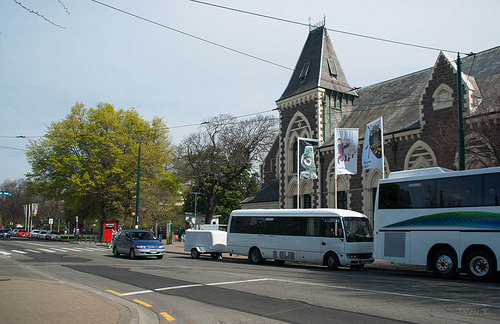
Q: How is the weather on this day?
A: It is clear.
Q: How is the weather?
A: It is clear.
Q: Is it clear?
A: Yes, it is clear.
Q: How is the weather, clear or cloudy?
A: It is clear.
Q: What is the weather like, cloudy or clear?
A: It is clear.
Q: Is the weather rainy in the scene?
A: No, it is clear.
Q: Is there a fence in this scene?
A: No, there are no fences.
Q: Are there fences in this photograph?
A: No, there are no fences.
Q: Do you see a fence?
A: No, there are no fences.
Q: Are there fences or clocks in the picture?
A: No, there are no fences or clocks.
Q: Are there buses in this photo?
A: Yes, there is a bus.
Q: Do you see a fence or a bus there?
A: Yes, there is a bus.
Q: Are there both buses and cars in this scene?
A: Yes, there are both a bus and a car.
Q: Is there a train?
A: No, there are no trains.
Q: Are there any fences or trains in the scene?
A: No, there are no trains or fences.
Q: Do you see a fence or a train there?
A: No, there are no trains or fences.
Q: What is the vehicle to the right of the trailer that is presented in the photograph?
A: The vehicle is a bus.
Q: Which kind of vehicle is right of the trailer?
A: The vehicle is a bus.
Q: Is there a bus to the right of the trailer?
A: Yes, there is a bus to the right of the trailer.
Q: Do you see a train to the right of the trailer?
A: No, there is a bus to the right of the trailer.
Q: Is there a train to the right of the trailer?
A: No, there is a bus to the right of the trailer.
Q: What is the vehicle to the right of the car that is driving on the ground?
A: The vehicle is a bus.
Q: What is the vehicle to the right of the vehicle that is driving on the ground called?
A: The vehicle is a bus.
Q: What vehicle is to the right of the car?
A: The vehicle is a bus.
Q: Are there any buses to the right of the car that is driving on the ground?
A: Yes, there is a bus to the right of the car.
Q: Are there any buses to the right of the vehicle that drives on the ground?
A: Yes, there is a bus to the right of the car.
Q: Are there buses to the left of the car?
A: No, the bus is to the right of the car.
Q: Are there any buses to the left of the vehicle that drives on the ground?
A: No, the bus is to the right of the car.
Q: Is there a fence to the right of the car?
A: No, there is a bus to the right of the car.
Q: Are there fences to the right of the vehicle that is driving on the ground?
A: No, there is a bus to the right of the car.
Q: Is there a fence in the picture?
A: No, there are no fences.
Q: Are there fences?
A: No, there are no fences.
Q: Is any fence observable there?
A: No, there are no fences.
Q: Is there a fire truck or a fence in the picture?
A: No, there are no fences or fire trucks.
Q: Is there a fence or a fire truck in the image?
A: No, there are no fences or fire trucks.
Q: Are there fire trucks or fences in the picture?
A: No, there are no fences or fire trucks.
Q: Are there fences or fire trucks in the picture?
A: No, there are no fences or fire trucks.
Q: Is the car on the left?
A: Yes, the car is on the left of the image.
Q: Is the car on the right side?
A: No, the car is on the left of the image.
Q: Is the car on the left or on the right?
A: The car is on the left of the image.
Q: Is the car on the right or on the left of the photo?
A: The car is on the left of the image.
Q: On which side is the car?
A: The car is on the left of the image.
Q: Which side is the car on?
A: The car is on the left of the image.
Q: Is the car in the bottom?
A: Yes, the car is in the bottom of the image.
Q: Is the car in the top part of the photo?
A: No, the car is in the bottom of the image.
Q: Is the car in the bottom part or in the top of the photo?
A: The car is in the bottom of the image.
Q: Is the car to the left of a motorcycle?
A: No, the car is to the left of the bus.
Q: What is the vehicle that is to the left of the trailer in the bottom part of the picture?
A: The vehicle is a car.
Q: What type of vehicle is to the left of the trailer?
A: The vehicle is a car.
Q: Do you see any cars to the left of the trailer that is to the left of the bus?
A: Yes, there is a car to the left of the trailer.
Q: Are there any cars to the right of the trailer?
A: No, the car is to the left of the trailer.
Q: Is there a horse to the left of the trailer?
A: No, there is a car to the left of the trailer.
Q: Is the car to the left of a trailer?
A: Yes, the car is to the left of a trailer.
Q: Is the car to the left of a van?
A: No, the car is to the left of a trailer.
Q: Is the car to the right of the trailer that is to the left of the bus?
A: No, the car is to the left of the trailer.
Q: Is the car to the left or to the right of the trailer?
A: The car is to the left of the trailer.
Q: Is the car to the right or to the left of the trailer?
A: The car is to the left of the trailer.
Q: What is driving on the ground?
A: The car is driving on the ground.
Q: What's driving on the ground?
A: The car is driving on the ground.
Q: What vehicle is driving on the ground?
A: The vehicle is a car.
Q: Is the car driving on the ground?
A: Yes, the car is driving on the ground.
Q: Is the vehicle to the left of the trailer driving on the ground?
A: Yes, the car is driving on the ground.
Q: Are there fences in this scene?
A: No, there are no fences.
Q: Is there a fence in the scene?
A: No, there are no fences.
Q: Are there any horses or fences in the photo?
A: No, there are no fences or horses.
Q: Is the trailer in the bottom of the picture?
A: Yes, the trailer is in the bottom of the image.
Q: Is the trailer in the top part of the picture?
A: No, the trailer is in the bottom of the image.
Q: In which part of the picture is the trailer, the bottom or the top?
A: The trailer is in the bottom of the image.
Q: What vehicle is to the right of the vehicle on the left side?
A: The vehicle is a trailer.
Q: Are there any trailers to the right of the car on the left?
A: Yes, there is a trailer to the right of the car.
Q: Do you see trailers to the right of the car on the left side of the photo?
A: Yes, there is a trailer to the right of the car.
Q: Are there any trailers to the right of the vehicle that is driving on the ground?
A: Yes, there is a trailer to the right of the car.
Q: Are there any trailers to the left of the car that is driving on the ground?
A: No, the trailer is to the right of the car.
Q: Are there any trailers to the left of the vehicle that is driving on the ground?
A: No, the trailer is to the right of the car.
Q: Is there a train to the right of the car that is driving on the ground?
A: No, there is a trailer to the right of the car.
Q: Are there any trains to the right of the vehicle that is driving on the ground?
A: No, there is a trailer to the right of the car.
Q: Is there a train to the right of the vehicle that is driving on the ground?
A: No, there is a trailer to the right of the car.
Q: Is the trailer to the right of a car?
A: Yes, the trailer is to the right of a car.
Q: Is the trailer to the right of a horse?
A: No, the trailer is to the right of a car.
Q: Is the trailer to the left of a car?
A: No, the trailer is to the right of a car.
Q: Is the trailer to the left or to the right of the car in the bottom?
A: The trailer is to the right of the car.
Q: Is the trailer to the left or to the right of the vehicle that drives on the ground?
A: The trailer is to the right of the car.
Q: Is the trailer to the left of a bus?
A: Yes, the trailer is to the left of a bus.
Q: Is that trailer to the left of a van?
A: No, the trailer is to the left of a bus.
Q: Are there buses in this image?
A: Yes, there is a bus.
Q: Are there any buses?
A: Yes, there is a bus.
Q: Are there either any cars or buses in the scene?
A: Yes, there is a bus.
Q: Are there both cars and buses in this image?
A: Yes, there are both a bus and a car.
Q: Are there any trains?
A: No, there are no trains.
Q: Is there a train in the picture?
A: No, there are no trains.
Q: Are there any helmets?
A: No, there are no helmets.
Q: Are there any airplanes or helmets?
A: No, there are no helmets or airplanes.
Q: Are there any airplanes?
A: No, there are no airplanes.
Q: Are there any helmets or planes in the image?
A: No, there are no planes or helmets.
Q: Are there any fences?
A: No, there are no fences.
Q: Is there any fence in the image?
A: No, there are no fences.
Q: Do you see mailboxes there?
A: No, there are no mailboxes.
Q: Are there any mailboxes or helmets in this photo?
A: No, there are no mailboxes or helmets.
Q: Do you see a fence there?
A: No, there are no fences.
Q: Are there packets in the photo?
A: No, there are no packets.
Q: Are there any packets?
A: No, there are no packets.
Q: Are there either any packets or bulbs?
A: No, there are no packets or bulbs.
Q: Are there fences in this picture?
A: No, there are no fences.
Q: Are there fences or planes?
A: No, there are no fences or planes.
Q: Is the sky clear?
A: Yes, the sky is clear.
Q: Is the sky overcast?
A: No, the sky is clear.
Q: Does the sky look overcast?
A: No, the sky is clear.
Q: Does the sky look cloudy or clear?
A: The sky is clear.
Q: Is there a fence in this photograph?
A: No, there are no fences.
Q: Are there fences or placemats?
A: No, there are no fences or placemats.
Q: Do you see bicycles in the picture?
A: No, there are no bicycles.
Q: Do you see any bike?
A: No, there are no bikes.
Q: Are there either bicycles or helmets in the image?
A: No, there are no bicycles or helmets.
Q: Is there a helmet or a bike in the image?
A: No, there are no bikes or helmets.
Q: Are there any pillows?
A: No, there are no pillows.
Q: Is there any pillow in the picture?
A: No, there are no pillows.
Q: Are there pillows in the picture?
A: No, there are no pillows.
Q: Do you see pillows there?
A: No, there are no pillows.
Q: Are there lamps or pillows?
A: No, there are no pillows or lamps.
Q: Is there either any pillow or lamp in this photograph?
A: No, there are no pillows or lamps.